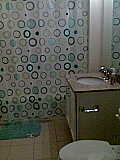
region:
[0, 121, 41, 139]
a bath mat on the floor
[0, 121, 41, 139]
the bath mat color is blue-green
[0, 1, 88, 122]
the shower curtain has a white background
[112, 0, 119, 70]
the shower curtain is reflected in the mirror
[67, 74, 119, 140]
the vanity is under the mirror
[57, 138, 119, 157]
the toilet is white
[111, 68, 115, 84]
a bottle on the side of the sink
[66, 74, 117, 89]
the top of the vanity is granite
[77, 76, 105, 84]
the sink is white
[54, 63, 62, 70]
the circle on the shower curtain is green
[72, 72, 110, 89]
a bathroom sink.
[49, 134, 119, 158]
a white toilet.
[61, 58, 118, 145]
a bathroom sink with faucet.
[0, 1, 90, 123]
a shower curtain.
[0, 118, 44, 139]
A rug near a shower.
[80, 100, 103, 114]
a metal toilet paper roller.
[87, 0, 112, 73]
a white section of wall.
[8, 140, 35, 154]
a tile on the floor.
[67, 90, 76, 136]
a door on a bathroom sink.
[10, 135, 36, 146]
a brown tile on a floor.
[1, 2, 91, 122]
bath tub curtain with circles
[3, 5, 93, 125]
shower curtain with blue circles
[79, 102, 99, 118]
empty toilet paper holder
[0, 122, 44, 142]
green bath tub mat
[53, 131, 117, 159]
white porcelain toilet lid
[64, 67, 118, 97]
brown bathroom counter top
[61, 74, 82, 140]
under sink storage cabinet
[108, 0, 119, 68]
reflection of shower curtain in mirror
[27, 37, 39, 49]
blue circle on shower curtain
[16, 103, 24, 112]
green circle on shower curtain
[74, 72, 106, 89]
a white bathroom sink.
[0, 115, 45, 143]
a bathroom floor rug.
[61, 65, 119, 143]
a bathroom sink.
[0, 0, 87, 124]
a multi colored shower curtain.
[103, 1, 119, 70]
a large bathroom mirror.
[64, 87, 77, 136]
a wooden door on a bathroom sink.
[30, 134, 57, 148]
a tile on a floor.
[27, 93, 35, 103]
a red circle on a shower curtain.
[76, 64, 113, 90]
sink in the photo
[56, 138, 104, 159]
toilet next to sink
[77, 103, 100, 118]
toilet paper holder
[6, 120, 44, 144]
mat on the ground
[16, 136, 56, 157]
floor next to sink and toilet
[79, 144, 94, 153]
white toilet seat lid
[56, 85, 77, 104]
cabinet under the sink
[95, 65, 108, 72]
faucet above the sink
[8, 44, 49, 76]
shower curtain next to sink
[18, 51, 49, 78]
circular designs on curtain